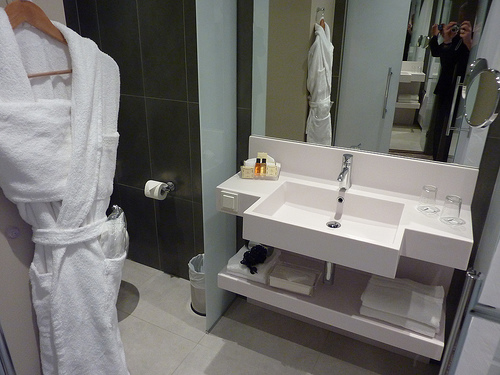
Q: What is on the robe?
A: White hanger.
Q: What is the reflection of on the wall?
A: Person talking a picture.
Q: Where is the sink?
A: Bathroom.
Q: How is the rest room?
A: Clean.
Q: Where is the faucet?
A: On sink.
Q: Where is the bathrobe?
A: On wall.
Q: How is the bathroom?
A: Fancy.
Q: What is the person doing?
A: Taking picture.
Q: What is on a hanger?
A: A bathrobe.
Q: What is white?
A: Sink.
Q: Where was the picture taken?
A: In a bathroom.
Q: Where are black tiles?
A: On the wall.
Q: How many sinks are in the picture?
A: One.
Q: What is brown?
A: A hanger.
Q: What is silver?
A: Faucet.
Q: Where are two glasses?
A: On the sink counter.